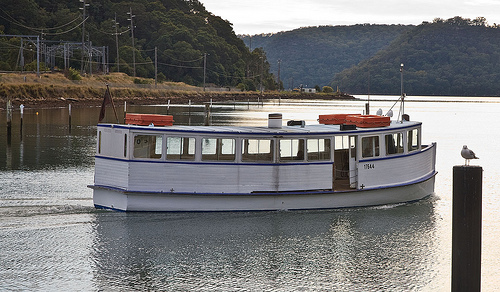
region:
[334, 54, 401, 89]
Section of a forest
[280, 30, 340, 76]
Section of a forest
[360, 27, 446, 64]
Section of a forest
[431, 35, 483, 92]
Section of a forest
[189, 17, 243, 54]
Section of a forest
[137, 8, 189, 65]
Section of a forest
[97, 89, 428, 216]
white ferry in water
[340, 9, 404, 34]
white clouds in blue sky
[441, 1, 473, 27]
white clouds in blue sky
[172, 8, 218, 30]
white clouds in blue sky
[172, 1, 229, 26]
white clouds in blue sky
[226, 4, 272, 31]
white clouds in blue sky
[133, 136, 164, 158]
window on white boat in water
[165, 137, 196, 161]
window on white boat in water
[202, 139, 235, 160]
window on white boat in water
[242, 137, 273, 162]
window on white boat in water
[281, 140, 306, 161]
window on white boat in water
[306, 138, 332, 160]
window on white boat in water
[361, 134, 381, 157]
window on white boat in water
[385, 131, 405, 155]
window on white boat in water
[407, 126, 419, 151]
window on white boat in water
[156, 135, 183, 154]
window on white boat in water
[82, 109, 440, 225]
white boat on body of water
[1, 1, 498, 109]
hills beyond body of water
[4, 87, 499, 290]
body of water near hills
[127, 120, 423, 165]
row of windows on boat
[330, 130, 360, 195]
entry door on boat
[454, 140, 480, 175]
bird standing on wooden post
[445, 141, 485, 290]
wooden post with bird on it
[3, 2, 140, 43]
wires on poles near water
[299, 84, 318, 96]
low white building in distance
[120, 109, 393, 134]
orange flotation devices on boat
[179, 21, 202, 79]
a tree in a distance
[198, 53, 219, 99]
a tree in a distance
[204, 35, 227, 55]
a tree in a distance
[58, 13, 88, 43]
a tree in a distance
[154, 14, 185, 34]
a tree in a distance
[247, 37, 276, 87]
a tree in a distance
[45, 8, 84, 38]
a tree in a distance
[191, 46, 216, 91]
This is a pole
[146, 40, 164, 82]
This is a pole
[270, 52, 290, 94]
This is a pole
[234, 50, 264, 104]
This is a pole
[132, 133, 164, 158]
glass window on the ship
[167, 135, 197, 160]
glass window on the ship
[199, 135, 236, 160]
glass window on the ship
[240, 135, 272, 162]
glass window on the ship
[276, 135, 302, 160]
glass window on the ship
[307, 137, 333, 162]
glass window on the ship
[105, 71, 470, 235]
a boat that is white in color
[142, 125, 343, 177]
the windows that are on a boat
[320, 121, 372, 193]
the door of a boat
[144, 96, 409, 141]
the roof of a boat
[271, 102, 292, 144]
the chimney of a boat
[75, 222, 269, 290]
some water in a river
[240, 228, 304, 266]
the ripples of a river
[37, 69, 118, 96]
some dirt that is brown in color